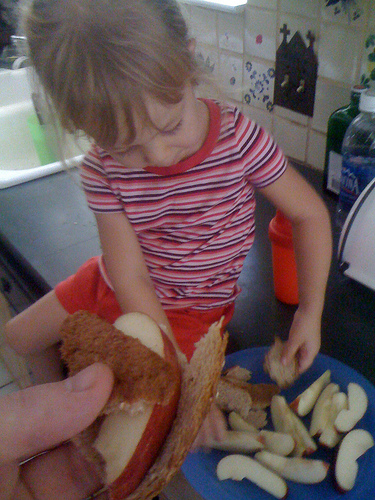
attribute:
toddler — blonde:
[5, 0, 331, 497]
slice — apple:
[268, 393, 313, 465]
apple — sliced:
[268, 392, 318, 462]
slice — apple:
[213, 451, 289, 496]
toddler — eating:
[2, 1, 337, 454]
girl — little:
[5, 0, 352, 377]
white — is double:
[6, 111, 16, 134]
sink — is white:
[0, 74, 26, 173]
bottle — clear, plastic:
[334, 85, 374, 245]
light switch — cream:
[295, 78, 306, 94]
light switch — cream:
[279, 73, 289, 90]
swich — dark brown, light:
[272, 61, 314, 116]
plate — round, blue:
[195, 468, 212, 490]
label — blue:
[336, 156, 363, 196]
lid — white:
[356, 90, 363, 101]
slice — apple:
[340, 424, 363, 496]